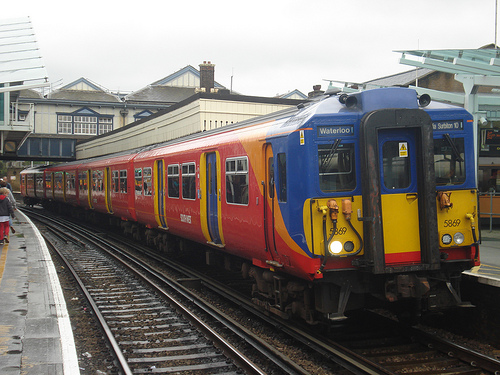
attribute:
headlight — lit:
[323, 239, 343, 255]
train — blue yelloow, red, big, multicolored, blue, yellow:
[19, 87, 486, 328]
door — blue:
[198, 150, 225, 242]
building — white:
[70, 90, 306, 160]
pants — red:
[1, 221, 12, 242]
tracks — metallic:
[16, 205, 268, 374]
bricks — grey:
[0, 213, 64, 375]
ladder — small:
[269, 272, 283, 309]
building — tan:
[0, 62, 308, 160]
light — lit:
[326, 239, 341, 256]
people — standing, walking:
[0, 177, 17, 246]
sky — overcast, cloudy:
[0, 1, 499, 99]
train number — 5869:
[443, 216, 463, 227]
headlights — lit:
[328, 230, 465, 252]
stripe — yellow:
[0, 238, 10, 283]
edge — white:
[16, 205, 80, 374]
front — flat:
[297, 80, 486, 307]